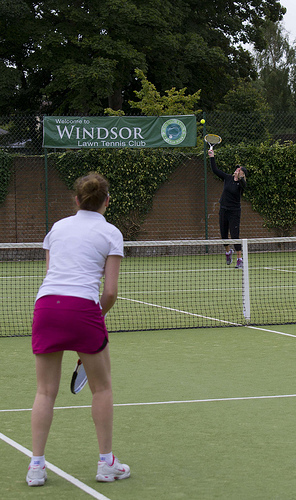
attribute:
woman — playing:
[27, 175, 128, 500]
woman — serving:
[192, 131, 250, 268]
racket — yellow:
[199, 131, 226, 162]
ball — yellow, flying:
[199, 117, 209, 123]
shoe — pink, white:
[86, 458, 136, 487]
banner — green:
[36, 115, 203, 154]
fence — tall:
[5, 142, 292, 255]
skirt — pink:
[29, 292, 108, 360]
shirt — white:
[29, 208, 125, 302]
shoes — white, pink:
[23, 447, 134, 493]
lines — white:
[2, 391, 295, 499]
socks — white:
[29, 453, 116, 466]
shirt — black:
[208, 162, 249, 218]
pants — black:
[214, 202, 245, 255]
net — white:
[4, 234, 296, 335]